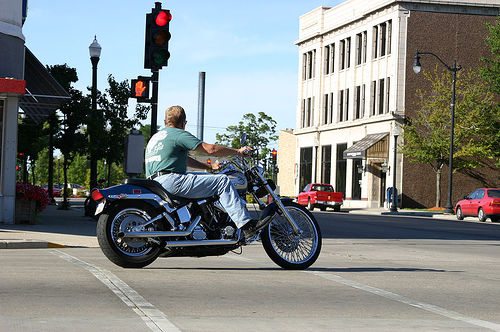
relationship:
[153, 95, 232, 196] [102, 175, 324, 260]
man riding motorcycle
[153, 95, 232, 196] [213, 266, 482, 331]
man at intersection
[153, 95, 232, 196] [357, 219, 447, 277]
man on street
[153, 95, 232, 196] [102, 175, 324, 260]
man on motorcycle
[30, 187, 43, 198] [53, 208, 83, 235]
bush on sidewalk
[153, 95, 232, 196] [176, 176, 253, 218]
man wearing jeans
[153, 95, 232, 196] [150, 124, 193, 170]
man wearing shirt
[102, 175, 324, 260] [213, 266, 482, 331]
motorcycle on intersection